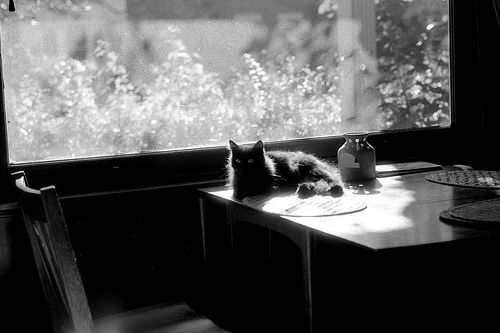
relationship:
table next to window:
[195, 160, 499, 332] [2, 3, 468, 191]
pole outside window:
[322, 4, 373, 136] [4, 0, 461, 171]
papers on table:
[357, 157, 441, 179] [195, 160, 499, 332]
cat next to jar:
[223, 139, 341, 199] [335, 136, 360, 189]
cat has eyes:
[223, 139, 341, 199] [227, 141, 262, 171]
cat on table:
[223, 136, 341, 198] [195, 157, 497, 272]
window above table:
[4, 0, 461, 171] [202, 159, 496, 318]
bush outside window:
[3, 24, 334, 156] [2, 3, 468, 191]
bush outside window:
[375, 0, 451, 127] [2, 3, 468, 191]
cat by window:
[223, 139, 341, 199] [4, 0, 461, 171]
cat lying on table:
[223, 139, 341, 199] [194, 156, 452, 331]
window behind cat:
[4, 0, 461, 171] [223, 136, 341, 198]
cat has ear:
[223, 139, 341, 199] [253, 139, 262, 147]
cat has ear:
[223, 139, 341, 199] [229, 140, 240, 151]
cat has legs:
[223, 139, 341, 199] [230, 183, 279, 202]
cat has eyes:
[223, 139, 341, 199] [232, 154, 255, 164]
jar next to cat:
[333, 128, 381, 184] [223, 139, 341, 199]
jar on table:
[333, 128, 381, 184] [195, 160, 499, 332]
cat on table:
[223, 139, 341, 199] [195, 160, 499, 332]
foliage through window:
[1, 38, 357, 163] [4, 0, 461, 171]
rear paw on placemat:
[327, 169, 344, 193] [242, 184, 363, 226]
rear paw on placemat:
[292, 174, 315, 199] [242, 184, 363, 226]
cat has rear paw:
[223, 139, 341, 199] [327, 169, 344, 193]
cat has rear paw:
[223, 139, 341, 199] [292, 174, 315, 199]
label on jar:
[338, 150, 360, 170] [336, 129, 378, 184]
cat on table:
[223, 139, 341, 199] [202, 159, 496, 318]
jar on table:
[334, 133, 376, 184] [202, 159, 496, 318]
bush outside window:
[3, 0, 342, 165] [4, 0, 461, 171]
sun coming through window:
[42, 40, 461, 218] [2, 9, 483, 179]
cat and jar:
[223, 139, 341, 199] [328, 125, 384, 187]